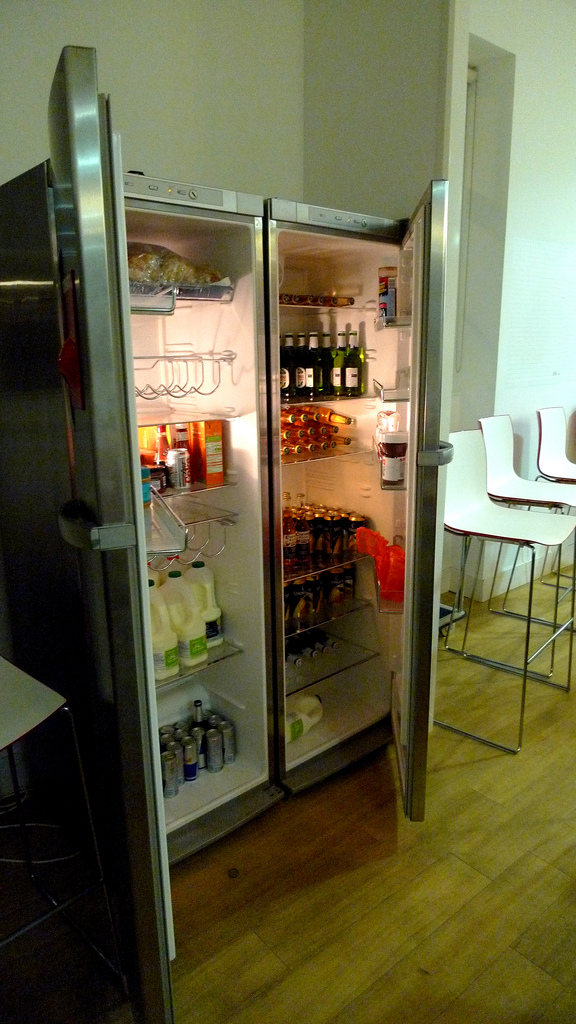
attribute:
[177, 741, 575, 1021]
floors — wooden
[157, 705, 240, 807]
cans — silver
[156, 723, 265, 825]
shelf — bottom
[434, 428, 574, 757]
chair — white, bar height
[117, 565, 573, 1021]
floor — medium colored, hard wood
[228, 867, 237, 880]
knot — dark brown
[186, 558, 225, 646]
milk — jug 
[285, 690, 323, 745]
milk — jug 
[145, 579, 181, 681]
milk — jug 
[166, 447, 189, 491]
diet coke — can 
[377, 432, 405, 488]
nuttella —  bottle 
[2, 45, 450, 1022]
refrigerator — stainless steel, double door, commercial 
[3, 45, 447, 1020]
fridge — steel , open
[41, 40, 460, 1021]
doors — open